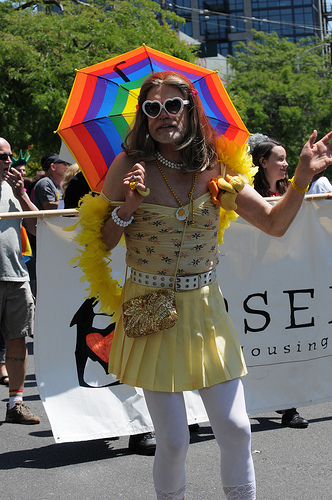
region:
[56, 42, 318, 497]
man dressed in women's clothing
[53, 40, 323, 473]
person holding a rainbow striped umbrella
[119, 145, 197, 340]
golden sequin purse across shoulder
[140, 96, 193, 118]
white heart sunglasses covering eyes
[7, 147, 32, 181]
boy wearing Statue of Liberty hat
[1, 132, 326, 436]
several people walking behind banner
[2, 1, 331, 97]
building with several windows is behind trees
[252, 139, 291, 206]
girl with brown hair is smiling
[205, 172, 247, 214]
duck stuffed animal attached to dress strap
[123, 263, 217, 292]
white belt with several holes around a waist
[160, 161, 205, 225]
a yellow beaded necklace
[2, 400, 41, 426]
a man's tennis shoe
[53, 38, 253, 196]
a small colorful umbrella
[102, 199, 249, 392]
a yellow dress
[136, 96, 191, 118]
white heart sunglasses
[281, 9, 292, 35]
a window of a building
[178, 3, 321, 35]
a long electrical power line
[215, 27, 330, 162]
a tall green tree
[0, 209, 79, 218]
a long brown pole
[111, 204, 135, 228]
a white beaded bracelet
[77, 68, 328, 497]
a man in a yellow dress and white leggings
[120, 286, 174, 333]
the gold purse of the man in yellow dress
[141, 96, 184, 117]
white heart shaped sunglasses man in dress is wearing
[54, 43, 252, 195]
rainbow colored umbrella man in yellow dress is carrying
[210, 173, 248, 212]
small stuffed toy duck on the man's chest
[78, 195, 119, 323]
yellow boa on the left on the man in yellow dress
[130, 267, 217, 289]
white belt on the man in the yellow dress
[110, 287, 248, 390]
yellow pleated bottom of the man in yellow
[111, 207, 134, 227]
white bracelet on the man in yellow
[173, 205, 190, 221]
white and yellow daisy pin on man in yellow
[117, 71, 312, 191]
Man with sunglasses.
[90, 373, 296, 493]
Man with white leggings.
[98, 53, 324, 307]
Man in a dress.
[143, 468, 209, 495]
Lace on the leggings.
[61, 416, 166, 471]
shadow on the ground.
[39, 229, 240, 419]
Purse on the man.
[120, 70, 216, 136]
Heart shaped sunglasses on the man.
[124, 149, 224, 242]
Necklace on the man.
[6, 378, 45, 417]
rainbow socks on the man.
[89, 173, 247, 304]
Belt on the man.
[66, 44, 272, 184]
a rainbow colored umbrella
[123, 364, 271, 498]
strechy white lace leggings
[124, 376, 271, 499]
a pair of man's legs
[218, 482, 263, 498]
white lace cuff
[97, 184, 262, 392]
a yellow short dress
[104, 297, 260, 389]
yellow pleated skirt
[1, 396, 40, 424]
a brown tied shoe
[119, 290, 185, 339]
a gold sequinced purse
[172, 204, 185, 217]
a white daisy with a yellow center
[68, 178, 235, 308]
a yellow feather boa